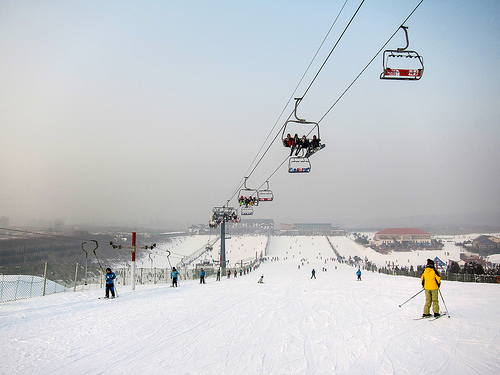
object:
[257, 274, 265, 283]
skiers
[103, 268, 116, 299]
skier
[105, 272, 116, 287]
coat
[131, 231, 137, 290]
pole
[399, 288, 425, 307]
extended pole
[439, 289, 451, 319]
extended pole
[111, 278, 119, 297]
extended pole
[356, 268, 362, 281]
people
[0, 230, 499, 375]
snow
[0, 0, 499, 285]
gray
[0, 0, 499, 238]
sky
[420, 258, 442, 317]
person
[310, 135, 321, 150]
people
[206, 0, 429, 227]
ski lift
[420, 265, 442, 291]
parka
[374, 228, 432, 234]
roof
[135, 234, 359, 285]
hill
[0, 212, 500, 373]
area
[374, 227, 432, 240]
building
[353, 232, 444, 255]
trees